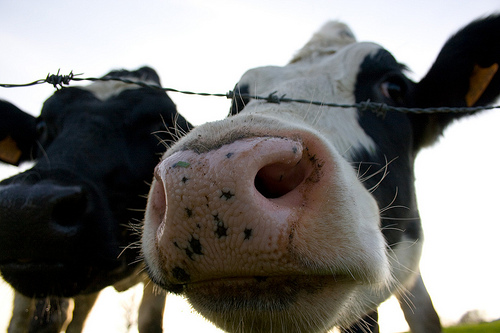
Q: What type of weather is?
A: It is clear.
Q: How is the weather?
A: It is clear.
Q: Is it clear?
A: Yes, it is clear.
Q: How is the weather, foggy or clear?
A: It is clear.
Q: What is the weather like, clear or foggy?
A: It is clear.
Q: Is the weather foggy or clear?
A: It is clear.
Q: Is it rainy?
A: No, it is clear.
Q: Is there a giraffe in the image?
A: No, there are no giraffes.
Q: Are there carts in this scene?
A: No, there are no carts.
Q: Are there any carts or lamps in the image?
A: No, there are no carts or lamps.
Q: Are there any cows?
A: Yes, there is a cow.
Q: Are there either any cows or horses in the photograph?
A: Yes, there is a cow.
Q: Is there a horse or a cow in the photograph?
A: Yes, there is a cow.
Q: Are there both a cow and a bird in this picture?
A: No, there is a cow but no birds.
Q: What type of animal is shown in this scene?
A: The animal is a cow.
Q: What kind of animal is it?
A: The animal is a cow.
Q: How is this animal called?
A: This is a cow.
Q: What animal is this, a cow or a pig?
A: This is a cow.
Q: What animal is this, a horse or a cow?
A: This is a cow.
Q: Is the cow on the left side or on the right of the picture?
A: The cow is on the left of the image.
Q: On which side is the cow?
A: The cow is on the left of the image.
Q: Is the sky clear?
A: Yes, the sky is clear.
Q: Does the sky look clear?
A: Yes, the sky is clear.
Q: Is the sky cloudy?
A: No, the sky is clear.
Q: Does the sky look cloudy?
A: No, the sky is clear.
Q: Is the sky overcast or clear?
A: The sky is clear.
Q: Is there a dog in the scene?
A: No, there are no dogs.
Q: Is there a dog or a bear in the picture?
A: No, there are no dogs or bears.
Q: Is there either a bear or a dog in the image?
A: No, there are no dogs or bears.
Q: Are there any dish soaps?
A: No, there are no dish soaps.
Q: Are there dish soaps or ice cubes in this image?
A: No, there are no dish soaps or ice cubes.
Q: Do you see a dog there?
A: No, there are no dogs.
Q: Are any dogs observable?
A: No, there are no dogs.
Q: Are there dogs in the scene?
A: No, there are no dogs.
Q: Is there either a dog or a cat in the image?
A: No, there are no dogs or cats.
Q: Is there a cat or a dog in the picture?
A: No, there are no dogs or cats.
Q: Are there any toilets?
A: No, there are no toilets.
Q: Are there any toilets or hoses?
A: No, there are no toilets or hoses.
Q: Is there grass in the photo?
A: Yes, there is grass.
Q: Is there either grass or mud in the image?
A: Yes, there is grass.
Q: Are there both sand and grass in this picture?
A: No, there is grass but no sand.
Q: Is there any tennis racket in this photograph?
A: No, there are no rackets.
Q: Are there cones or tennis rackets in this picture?
A: No, there are no tennis rackets or cones.